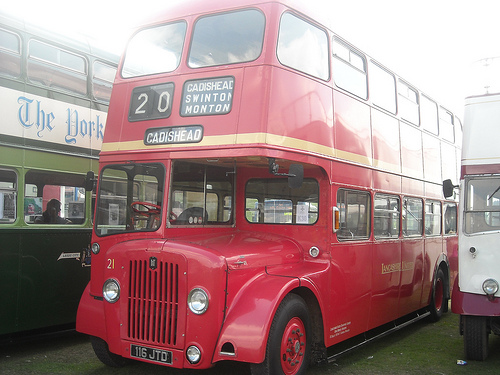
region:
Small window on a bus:
[237, 173, 321, 229]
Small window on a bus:
[330, 181, 372, 246]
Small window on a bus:
[370, 187, 402, 243]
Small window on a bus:
[399, 191, 422, 240]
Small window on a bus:
[422, 198, 442, 235]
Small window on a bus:
[438, 196, 458, 253]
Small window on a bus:
[328, 29, 368, 111]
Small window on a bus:
[365, 47, 397, 118]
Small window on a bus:
[395, 69, 424, 124]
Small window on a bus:
[153, 148, 240, 233]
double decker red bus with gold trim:
[76, 1, 465, 371]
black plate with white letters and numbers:
[126, 342, 172, 368]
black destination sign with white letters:
[143, 123, 205, 145]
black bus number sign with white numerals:
[126, 79, 175, 122]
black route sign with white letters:
[179, 76, 234, 118]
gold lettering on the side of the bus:
[374, 257, 427, 273]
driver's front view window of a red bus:
[94, 158, 168, 237]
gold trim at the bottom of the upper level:
[102, 132, 462, 193]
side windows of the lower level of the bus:
[333, 182, 462, 242]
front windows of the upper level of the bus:
[119, 4, 266, 80]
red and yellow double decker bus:
[74, 1, 457, 364]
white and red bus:
[457, 84, 497, 372]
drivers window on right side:
[100, 166, 168, 232]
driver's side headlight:
[99, 278, 119, 299]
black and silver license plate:
[128, 343, 175, 364]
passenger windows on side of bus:
[376, 186, 457, 238]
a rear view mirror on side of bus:
[437, 172, 459, 201]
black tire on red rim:
[271, 290, 313, 374]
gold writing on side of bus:
[380, 255, 434, 275]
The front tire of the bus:
[271, 293, 316, 374]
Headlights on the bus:
[102, 278, 210, 315]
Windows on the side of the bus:
[333, 185, 454, 240]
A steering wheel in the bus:
[132, 199, 173, 226]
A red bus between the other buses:
[76, 0, 458, 374]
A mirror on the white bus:
[441, 178, 453, 198]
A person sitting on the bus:
[42, 198, 70, 222]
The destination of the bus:
[181, 79, 232, 112]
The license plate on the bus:
[131, 341, 170, 364]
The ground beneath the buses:
[1, 309, 496, 374]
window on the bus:
[278, 24, 322, 81]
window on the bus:
[338, 193, 363, 243]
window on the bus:
[256, 180, 313, 222]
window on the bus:
[188, 173, 229, 221]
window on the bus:
[114, 175, 154, 231]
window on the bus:
[369, 195, 396, 241]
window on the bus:
[332, 57, 360, 92]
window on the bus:
[373, 68, 395, 107]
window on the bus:
[396, 90, 416, 120]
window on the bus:
[423, 102, 436, 127]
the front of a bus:
[90, 53, 285, 348]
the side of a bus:
[257, 11, 489, 351]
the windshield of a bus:
[77, 165, 227, 257]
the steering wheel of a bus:
[112, 189, 184, 236]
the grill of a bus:
[135, 245, 200, 360]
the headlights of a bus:
[87, 269, 227, 329]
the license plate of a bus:
[115, 333, 179, 368]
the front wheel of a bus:
[264, 295, 321, 373]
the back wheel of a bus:
[417, 271, 449, 316]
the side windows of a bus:
[315, 182, 443, 243]